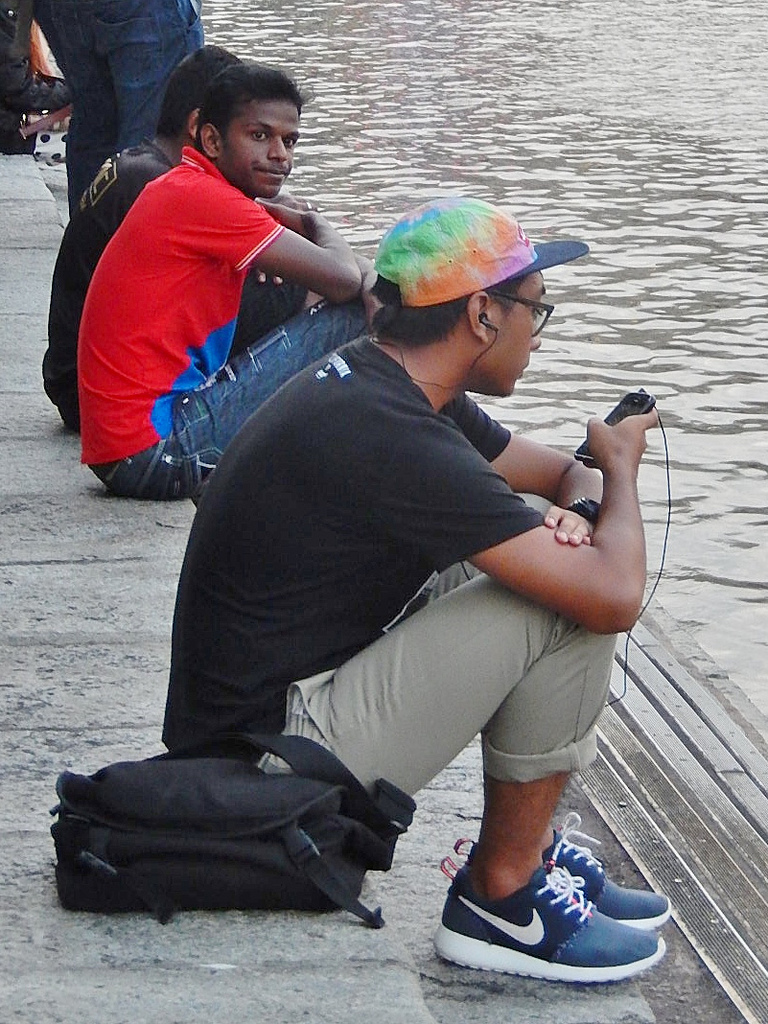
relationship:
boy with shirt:
[70, 54, 379, 530] [72, 163, 321, 482]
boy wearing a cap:
[167, 164, 729, 986] [353, 164, 600, 362]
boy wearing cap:
[160, 197, 674, 985] [374, 192, 589, 308]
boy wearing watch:
[160, 197, 674, 985] [564, 494, 611, 522]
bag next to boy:
[50, 728, 417, 925] [157, 191, 677, 987]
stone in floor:
[7, 944, 437, 1018] [1, 163, 442, 1020]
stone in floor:
[4, 820, 418, 970] [0, 150, 639, 1019]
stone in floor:
[4, 725, 179, 824] [1, 163, 442, 1020]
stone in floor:
[0, 194, 70, 246] [10, 401, 181, 712]